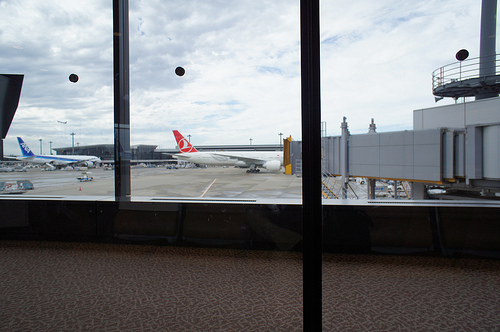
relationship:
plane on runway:
[171, 127, 283, 175] [0, 165, 365, 201]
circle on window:
[174, 67, 186, 77] [131, 1, 303, 205]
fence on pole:
[295, 129, 461, 183] [340, 115, 350, 197]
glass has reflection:
[0, 4, 496, 331] [112, 187, 498, 255]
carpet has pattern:
[0, 238, 500, 331] [2, 236, 500, 332]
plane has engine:
[171, 127, 283, 175] [264, 158, 283, 174]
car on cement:
[77, 167, 94, 183] [43, 169, 178, 200]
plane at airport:
[171, 127, 283, 175] [0, 129, 499, 207]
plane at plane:
[171, 127, 283, 175] [162, 130, 284, 174]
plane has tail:
[171, 127, 283, 175] [174, 128, 201, 154]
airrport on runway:
[1, 137, 103, 172] [0, 165, 365, 201]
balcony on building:
[431, 51, 499, 102] [413, 0, 499, 177]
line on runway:
[201, 175, 217, 200] [0, 165, 365, 201]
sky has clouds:
[0, 2, 499, 150] [10, 2, 478, 152]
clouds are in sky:
[10, 2, 478, 152] [0, 2, 499, 150]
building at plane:
[55, 142, 179, 167] [162, 130, 284, 174]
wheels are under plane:
[245, 168, 261, 174] [171, 127, 283, 175]